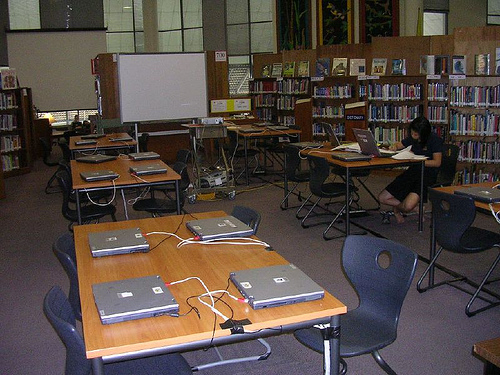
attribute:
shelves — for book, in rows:
[271, 64, 499, 151]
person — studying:
[401, 113, 444, 163]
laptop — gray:
[230, 257, 337, 329]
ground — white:
[391, 148, 437, 173]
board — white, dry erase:
[77, 34, 212, 119]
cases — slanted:
[245, 33, 495, 192]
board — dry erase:
[115, 49, 211, 125]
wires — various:
[190, 141, 243, 203]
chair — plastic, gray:
[298, 234, 416, 374]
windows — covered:
[12, 6, 282, 58]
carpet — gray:
[1, 152, 499, 374]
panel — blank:
[114, 47, 209, 126]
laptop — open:
[354, 125, 403, 157]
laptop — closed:
[187, 211, 254, 241]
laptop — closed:
[89, 224, 150, 258]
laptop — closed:
[91, 269, 180, 324]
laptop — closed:
[231, 266, 325, 309]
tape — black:
[216, 315, 249, 335]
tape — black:
[314, 324, 343, 342]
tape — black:
[264, 242, 274, 252]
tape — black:
[256, 348, 272, 364]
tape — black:
[191, 364, 202, 373]